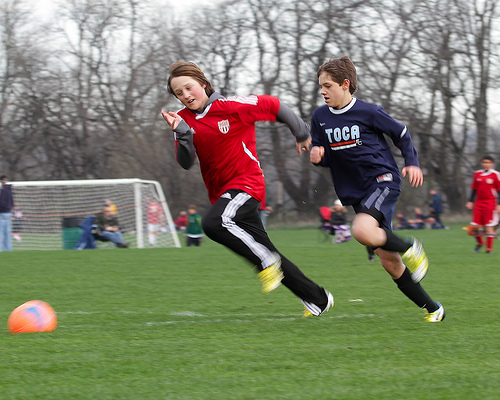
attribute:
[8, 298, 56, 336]
soccer ball — blue, flat, orange, large, moving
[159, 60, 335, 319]
boy — running, running up, playing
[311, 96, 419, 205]
jersey — blue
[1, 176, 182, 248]
soccer net — white, waiting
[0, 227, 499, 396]
grass — green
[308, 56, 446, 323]
boy — running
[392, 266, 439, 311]
sock — black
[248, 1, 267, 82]
branch — tall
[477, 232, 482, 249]
sock — red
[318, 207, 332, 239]
chair — red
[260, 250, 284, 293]
shoe — white, yellow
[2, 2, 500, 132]
sky — white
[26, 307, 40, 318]
spot — blue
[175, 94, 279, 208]
shirt — red, white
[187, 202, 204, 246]
person — kneeling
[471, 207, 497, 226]
shorts — red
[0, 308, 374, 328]
line — white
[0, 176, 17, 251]
man — standing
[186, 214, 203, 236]
shirt — white, green